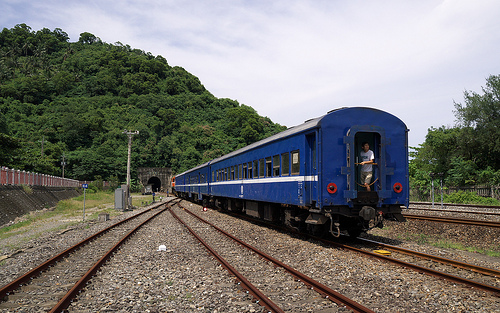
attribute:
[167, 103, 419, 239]
train — blue, long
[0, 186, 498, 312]
tracks — rocky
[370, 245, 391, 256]
something — yellow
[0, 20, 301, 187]
trees — green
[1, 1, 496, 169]
sky — blue, cloudy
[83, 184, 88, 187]
sign — blue, small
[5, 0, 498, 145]
clouds — white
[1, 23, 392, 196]
leaves — green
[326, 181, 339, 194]
headlight — red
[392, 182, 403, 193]
headlight — red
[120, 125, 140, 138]
wire — electric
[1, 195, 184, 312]
tracks — railroad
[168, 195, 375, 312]
tracks — railroad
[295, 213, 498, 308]
tracks — railroad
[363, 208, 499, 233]
tracks — railroad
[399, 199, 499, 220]
tracks — railroad